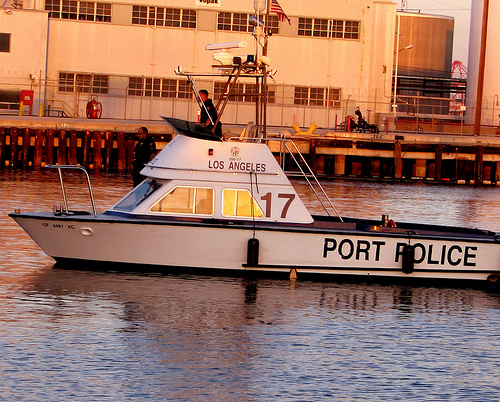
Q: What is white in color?
A: The boat.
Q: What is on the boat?
A: Writing.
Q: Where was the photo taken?
A: Water.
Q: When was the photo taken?
A: During the daytime.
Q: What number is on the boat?
A: 17.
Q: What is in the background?
A: A building.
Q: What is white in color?
A: The ladder.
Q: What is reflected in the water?
A: The boat.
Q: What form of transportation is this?
A: Boat.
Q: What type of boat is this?
A: Police boat.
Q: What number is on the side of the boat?
A: 17.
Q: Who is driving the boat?
A: A police officer.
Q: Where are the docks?
A: Behind the boat.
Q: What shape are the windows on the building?
A: Square.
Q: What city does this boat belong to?
A: Los Angeles.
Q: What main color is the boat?
A: White.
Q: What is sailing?
A: Police boat.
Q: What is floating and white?
A: Boat.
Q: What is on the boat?
A: Police.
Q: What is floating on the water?
A: Boat.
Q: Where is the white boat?
A: On the water.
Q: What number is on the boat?
A: 17.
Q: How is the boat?
A: White.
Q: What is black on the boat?
A: Letters.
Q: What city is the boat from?
A: Los Angeles.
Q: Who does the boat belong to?
A: The police.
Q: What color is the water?
A: Blue.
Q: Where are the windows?
A: On the boat and the building.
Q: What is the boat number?
A: 17.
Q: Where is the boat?
A: In the water.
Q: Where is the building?
A: Adjoining the water.